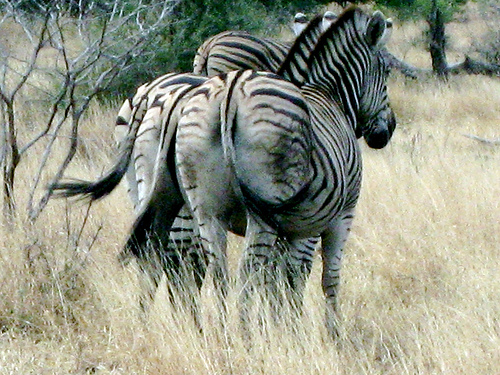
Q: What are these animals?
A: Zebras.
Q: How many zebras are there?
A: Two.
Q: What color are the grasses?
A: Brown.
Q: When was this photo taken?
A: In the daytime.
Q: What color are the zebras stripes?
A: Black and white.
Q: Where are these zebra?
A: In a field.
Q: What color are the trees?
A: Green.